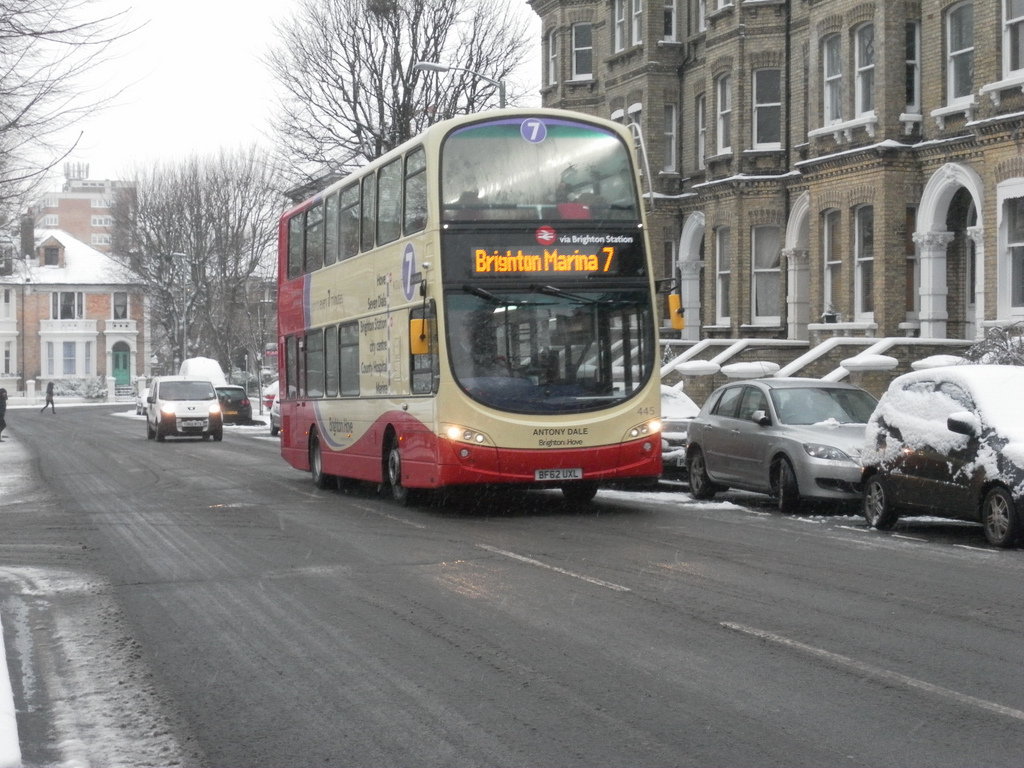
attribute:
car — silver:
[676, 376, 884, 519]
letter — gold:
[473, 243, 489, 272]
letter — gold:
[486, 256, 495, 272]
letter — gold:
[497, 253, 508, 271]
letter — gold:
[540, 245, 560, 272]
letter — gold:
[586, 253, 600, 273]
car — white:
[143, 370, 226, 444]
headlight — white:
[160, 404, 178, 417]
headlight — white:
[207, 404, 225, 417]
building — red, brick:
[4, 208, 156, 405]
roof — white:
[4, 223, 154, 284]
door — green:
[110, 340, 134, 388]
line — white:
[475, 538, 635, 593]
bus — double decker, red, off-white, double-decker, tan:
[272, 104, 670, 504]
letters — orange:
[460, 217, 638, 285]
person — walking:
[24, 362, 68, 419]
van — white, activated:
[132, 360, 236, 453]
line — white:
[453, 496, 654, 630]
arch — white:
[913, 120, 993, 354]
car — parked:
[648, 314, 910, 529]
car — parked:
[192, 362, 268, 419]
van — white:
[140, 366, 236, 440]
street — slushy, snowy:
[11, 402, 1020, 765]